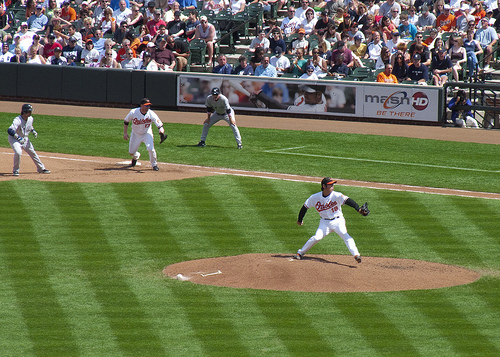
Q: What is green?
A: Grass.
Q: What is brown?
A: Dirt.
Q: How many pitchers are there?
A: One.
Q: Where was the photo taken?
A: At a baseball game.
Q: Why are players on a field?
A: To play baseball.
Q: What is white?
A: Pitcher's uniform.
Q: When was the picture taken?
A: Daytime.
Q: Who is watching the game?
A: Spectators.